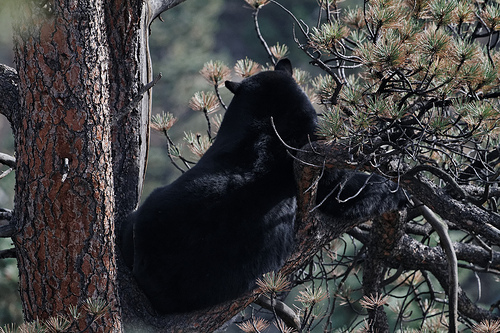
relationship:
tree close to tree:
[3, 2, 122, 331] [107, 3, 146, 216]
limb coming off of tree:
[143, 66, 163, 93] [102, 0, 159, 245]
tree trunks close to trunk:
[0, 0, 123, 333] [104, 1, 151, 238]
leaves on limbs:
[293, 2, 499, 172] [295, 34, 480, 197]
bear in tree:
[131, 57, 415, 315] [1, 0, 499, 331]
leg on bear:
[311, 165, 409, 220] [116, 57, 393, 315]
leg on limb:
[311, 165, 409, 220] [287, 139, 494, 238]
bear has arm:
[131, 57, 415, 315] [327, 169, 405, 216]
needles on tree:
[169, 10, 496, 216] [1, 0, 499, 331]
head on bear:
[222, 59, 316, 132] [131, 57, 415, 315]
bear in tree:
[93, 43, 463, 332] [1, 0, 499, 331]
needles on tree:
[358, 47, 468, 153] [1, 0, 499, 331]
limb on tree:
[415, 202, 460, 330] [9, 6, 148, 331]